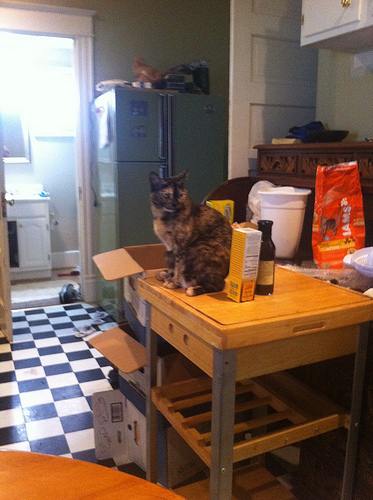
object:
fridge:
[90, 88, 230, 310]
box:
[225, 224, 262, 304]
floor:
[6, 309, 105, 463]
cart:
[133, 267, 371, 498]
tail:
[184, 276, 222, 297]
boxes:
[87, 241, 171, 346]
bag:
[311, 159, 364, 271]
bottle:
[250, 219, 276, 293]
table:
[131, 258, 371, 498]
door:
[300, 1, 361, 37]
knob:
[300, 16, 304, 25]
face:
[151, 176, 188, 211]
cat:
[146, 168, 233, 301]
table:
[0, 449, 194, 498]